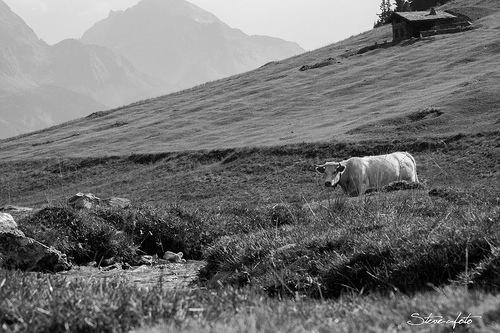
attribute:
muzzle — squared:
[322, 180, 333, 189]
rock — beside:
[0, 208, 73, 274]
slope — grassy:
[0, 16, 497, 163]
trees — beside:
[374, 2, 396, 24]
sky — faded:
[3, 0, 385, 82]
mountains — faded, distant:
[3, 0, 320, 134]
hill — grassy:
[152, 83, 497, 214]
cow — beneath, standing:
[314, 147, 421, 197]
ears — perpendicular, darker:
[316, 162, 348, 173]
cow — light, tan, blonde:
[313, 150, 414, 209]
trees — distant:
[370, 0, 457, 14]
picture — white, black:
[1, 0, 498, 331]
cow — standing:
[318, 152, 423, 193]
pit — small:
[344, 77, 474, 163]